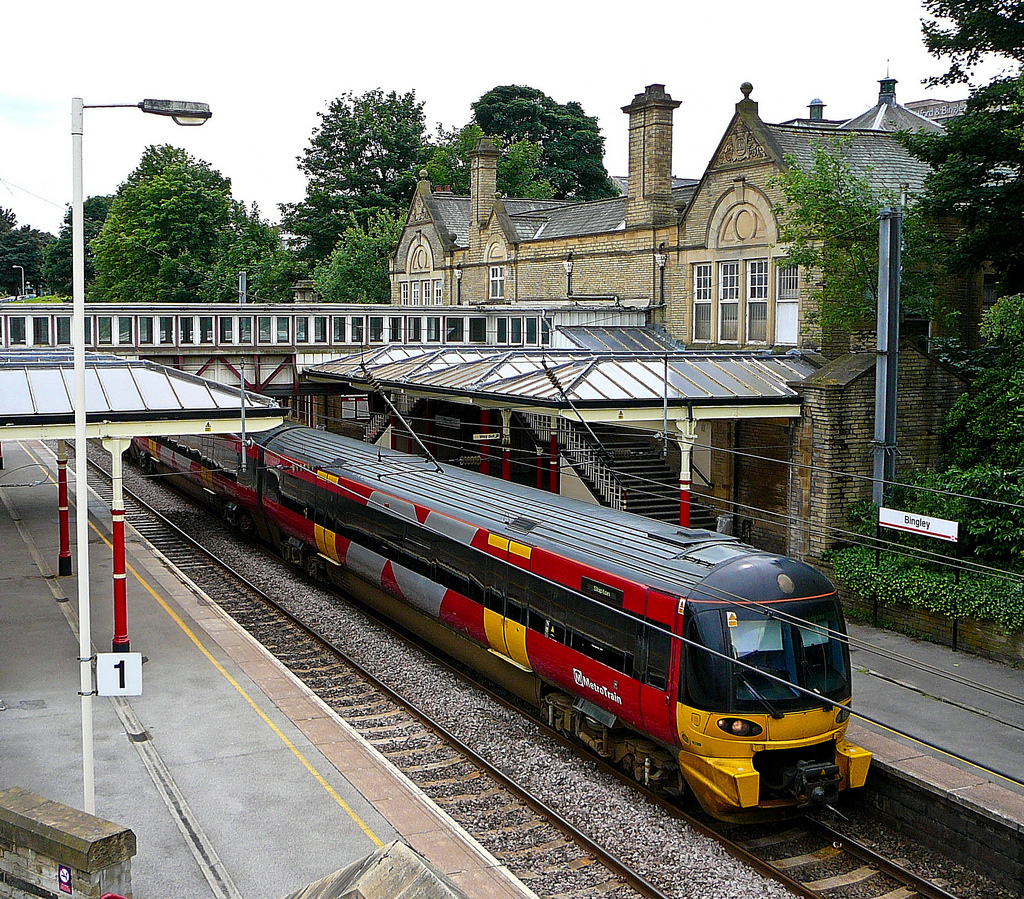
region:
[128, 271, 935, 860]
train on train tracks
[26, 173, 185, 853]
pole with a number 1 sign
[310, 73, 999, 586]
building on the side of a station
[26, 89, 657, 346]
row of trees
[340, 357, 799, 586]
set of two stair cases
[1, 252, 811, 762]
crosswalk above train tracks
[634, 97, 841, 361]
row of windows on a building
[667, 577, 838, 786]
the front end of a train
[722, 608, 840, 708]
the windshield of a train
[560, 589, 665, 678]
the passenger window of a train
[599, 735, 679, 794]
the wheels of a train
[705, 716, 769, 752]
the left headlight of a train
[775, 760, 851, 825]
the connecter of a train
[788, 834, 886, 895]
the tracks of a train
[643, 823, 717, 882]
a bunch of gray gravel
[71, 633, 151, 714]
sign with number 1 on i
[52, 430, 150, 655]
red poles by train tracks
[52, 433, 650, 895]
metal train tracks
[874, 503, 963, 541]
sign with writing on it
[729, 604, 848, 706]
windows on the front of train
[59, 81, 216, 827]
tall white street light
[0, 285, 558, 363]
bridge going across train top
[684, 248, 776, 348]
windows on the building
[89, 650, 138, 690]
a number on the post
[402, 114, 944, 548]
a brick building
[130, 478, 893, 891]
train tracks under the train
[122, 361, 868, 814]
a yellow and red train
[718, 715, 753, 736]
the headlight on the train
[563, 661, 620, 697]
writing on the train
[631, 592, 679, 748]
the door on the train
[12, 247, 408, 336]
A forest of trees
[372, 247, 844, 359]
The building to the right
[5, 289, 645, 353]
The metal bridge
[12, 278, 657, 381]
A metal bridge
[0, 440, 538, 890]
A platform to the left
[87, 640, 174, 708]
The number place card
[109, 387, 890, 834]
train parked on railroad tracks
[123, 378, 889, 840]
train on tracks is red and yellow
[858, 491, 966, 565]
sign above green shrubbery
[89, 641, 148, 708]
number sign hanging on pole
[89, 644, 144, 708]
number on pole is 1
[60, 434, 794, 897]
gravel next to train tracks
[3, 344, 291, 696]
awning over platform area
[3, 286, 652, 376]
bridge connected to large building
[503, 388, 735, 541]
steps under right awning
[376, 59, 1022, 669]
large building next to tracks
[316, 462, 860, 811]
The train on the track.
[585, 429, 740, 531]
Stairs to the platform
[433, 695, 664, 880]
gravel and rocks between the tracks.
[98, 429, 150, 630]
The pole is red and white.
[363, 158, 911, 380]
The building of the train station.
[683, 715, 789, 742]
left light of the train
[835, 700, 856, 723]
right light of the train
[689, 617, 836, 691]
frontal window of the train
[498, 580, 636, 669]
left side window of the train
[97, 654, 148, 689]
number of signaling station platform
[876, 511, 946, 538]
name signaling station platform